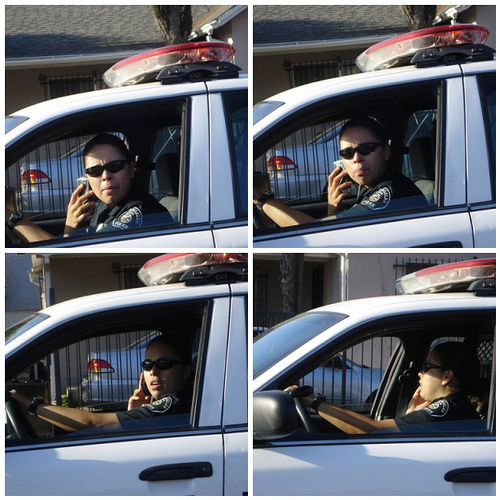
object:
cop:
[6, 136, 179, 246]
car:
[6, 40, 248, 253]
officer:
[255, 116, 429, 231]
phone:
[332, 160, 350, 190]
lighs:
[354, 23, 487, 73]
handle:
[409, 240, 463, 250]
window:
[252, 81, 441, 240]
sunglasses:
[339, 140, 386, 159]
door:
[256, 74, 473, 249]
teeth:
[354, 167, 369, 175]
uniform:
[338, 176, 429, 220]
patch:
[361, 185, 391, 211]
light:
[101, 40, 236, 88]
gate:
[6, 132, 130, 219]